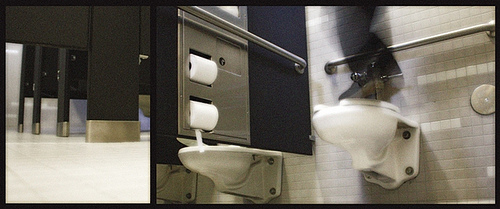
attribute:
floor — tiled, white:
[3, 113, 148, 202]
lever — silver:
[382, 72, 404, 80]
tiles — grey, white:
[265, 4, 496, 204]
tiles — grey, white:
[195, 171, 253, 203]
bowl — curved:
[311, 102, 413, 169]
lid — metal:
[451, 74, 496, 114]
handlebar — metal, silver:
[165, 11, 321, 83]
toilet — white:
[177, 141, 288, 203]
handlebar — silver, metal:
[327, 10, 492, 72]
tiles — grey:
[405, 47, 470, 148]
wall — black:
[267, 67, 305, 139]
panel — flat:
[397, 129, 414, 171]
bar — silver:
[320, 17, 495, 74]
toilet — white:
[305, 95, 425, 192]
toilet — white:
[159, 168, 196, 203]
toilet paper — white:
[187, 99, 218, 130]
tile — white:
[23, 162, 142, 198]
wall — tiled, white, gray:
[309, 8, 495, 206]